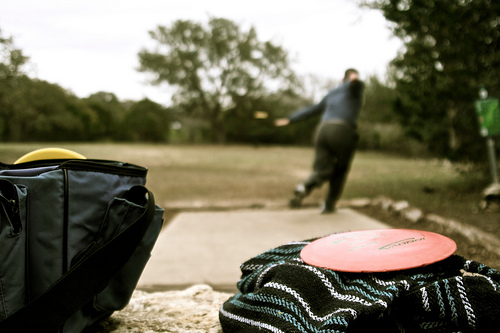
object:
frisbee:
[298, 219, 460, 276]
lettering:
[373, 230, 432, 252]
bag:
[0, 157, 164, 332]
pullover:
[212, 231, 495, 330]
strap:
[2, 182, 168, 332]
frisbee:
[5, 143, 93, 165]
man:
[269, 66, 368, 216]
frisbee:
[253, 108, 272, 122]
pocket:
[82, 184, 167, 319]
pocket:
[2, 176, 41, 322]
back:
[0, 165, 66, 332]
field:
[8, 137, 498, 262]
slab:
[137, 206, 396, 294]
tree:
[126, 11, 306, 155]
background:
[4, 0, 499, 151]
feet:
[286, 181, 343, 219]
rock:
[112, 283, 236, 332]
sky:
[9, 1, 401, 109]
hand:
[272, 114, 292, 136]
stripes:
[228, 282, 347, 332]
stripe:
[213, 304, 292, 332]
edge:
[12, 147, 94, 171]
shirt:
[290, 79, 369, 126]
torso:
[320, 85, 361, 133]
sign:
[474, 97, 499, 145]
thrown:
[256, 112, 273, 124]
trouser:
[289, 120, 359, 216]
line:
[168, 185, 498, 259]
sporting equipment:
[12, 138, 462, 286]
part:
[17, 5, 52, 27]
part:
[310, 121, 359, 156]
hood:
[218, 261, 391, 331]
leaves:
[140, 53, 179, 80]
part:
[98, 192, 143, 232]